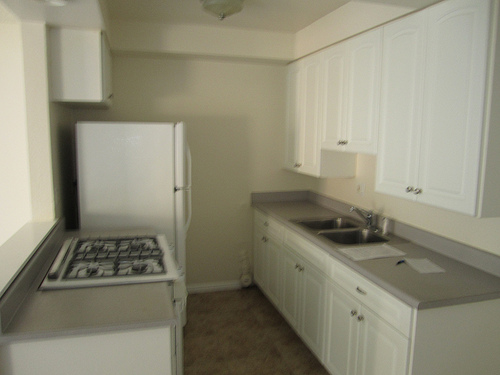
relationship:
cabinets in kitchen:
[281, 0, 500, 219] [8, 3, 476, 359]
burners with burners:
[39, 232, 179, 290] [39, 232, 179, 290]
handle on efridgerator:
[181, 141, 196, 232] [74, 117, 191, 331]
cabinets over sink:
[281, 0, 496, 216] [296, 209, 388, 250]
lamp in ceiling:
[203, 0, 239, 22] [103, 2, 383, 62]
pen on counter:
[395, 258, 406, 265] [247, 202, 500, 375]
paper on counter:
[335, 240, 409, 262] [247, 202, 500, 375]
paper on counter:
[402, 255, 447, 275] [247, 202, 500, 375]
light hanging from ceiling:
[198, 6, 255, 24] [24, 1, 402, 37]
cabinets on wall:
[281, 0, 500, 219] [280, 116, 498, 302]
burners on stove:
[55, 231, 170, 289] [50, 225, 186, 312]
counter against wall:
[247, 202, 500, 375] [301, 147, 498, 251]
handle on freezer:
[186, 144, 193, 232] [171, 117, 193, 187]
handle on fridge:
[186, 144, 193, 232] [173, 189, 191, 317]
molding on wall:
[184, 280, 246, 295] [186, 269, 258, 295]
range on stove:
[60, 234, 164, 278] [42, 232, 176, 288]